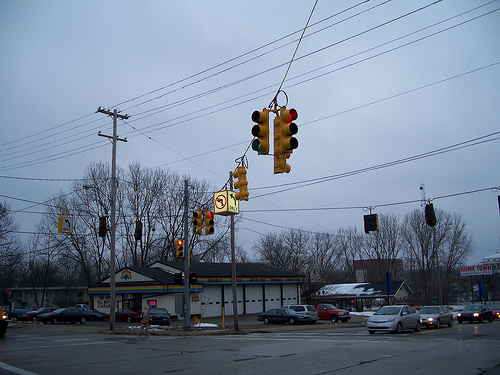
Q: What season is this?
A: Winter.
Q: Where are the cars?
A: At the intersection.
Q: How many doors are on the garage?
A: Five.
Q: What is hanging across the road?
A: Traffic lights.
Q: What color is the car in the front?
A: Grey.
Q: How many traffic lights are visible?
A: Nine.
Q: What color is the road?
A: Grey.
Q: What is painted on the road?
A: Stop lines.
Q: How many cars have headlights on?
A: Three.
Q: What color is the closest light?
A: Red.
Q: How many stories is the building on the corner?
A: One.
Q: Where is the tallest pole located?
A: At the corner.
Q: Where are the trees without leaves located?
A: Behind the traffic lights.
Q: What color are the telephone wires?
A: Black.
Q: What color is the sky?
A: Bluish gray.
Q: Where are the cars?
A: Stopping by the signal.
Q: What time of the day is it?
A: It's evening.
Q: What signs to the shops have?
A: Open sign.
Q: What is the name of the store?
A: Home Town.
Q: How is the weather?
A: Cloudy and rainy.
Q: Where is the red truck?
A: In the parking lot.